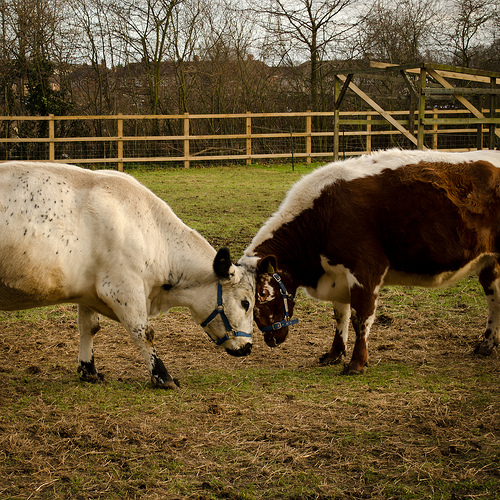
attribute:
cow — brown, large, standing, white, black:
[240, 139, 500, 374]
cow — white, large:
[0, 152, 258, 394]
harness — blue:
[203, 280, 252, 344]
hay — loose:
[0, 312, 482, 373]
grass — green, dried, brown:
[3, 165, 500, 499]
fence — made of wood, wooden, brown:
[1, 108, 499, 176]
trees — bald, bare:
[0, 1, 496, 107]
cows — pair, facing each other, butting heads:
[0, 120, 499, 390]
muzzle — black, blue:
[256, 264, 298, 336]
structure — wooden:
[332, 51, 499, 156]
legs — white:
[64, 296, 179, 391]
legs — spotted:
[321, 259, 383, 379]